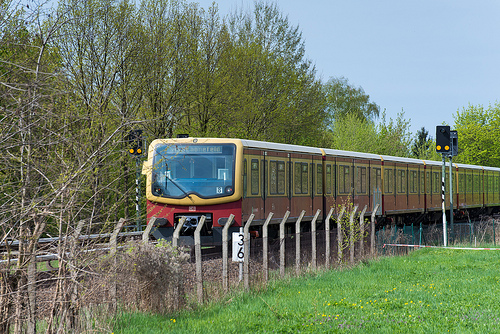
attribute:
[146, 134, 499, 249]
train — red, yellow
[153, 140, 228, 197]
windshield — large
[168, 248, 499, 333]
grass — green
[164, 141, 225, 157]
digital  board — train's destination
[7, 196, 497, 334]
fence — wooden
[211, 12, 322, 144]
tree — tall, green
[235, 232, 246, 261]
36 — black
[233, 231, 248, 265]
sign — white, square shaped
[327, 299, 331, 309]
flower — small, yellow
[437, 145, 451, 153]
lights — yellow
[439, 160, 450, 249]
pole — grey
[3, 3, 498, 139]
sky — blue, clear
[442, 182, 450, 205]
stripes — black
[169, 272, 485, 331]
flowers — yellow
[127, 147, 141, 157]
lights — yellow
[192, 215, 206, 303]
post — wooden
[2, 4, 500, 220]
trees — leafy